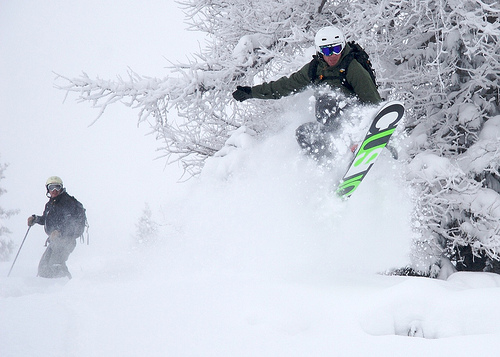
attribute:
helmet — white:
[317, 30, 342, 47]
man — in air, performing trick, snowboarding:
[275, 31, 398, 187]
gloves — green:
[237, 74, 260, 114]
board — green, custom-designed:
[317, 104, 401, 216]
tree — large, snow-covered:
[58, 15, 498, 180]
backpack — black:
[334, 32, 377, 76]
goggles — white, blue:
[295, 44, 356, 57]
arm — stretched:
[224, 57, 318, 111]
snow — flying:
[291, 106, 372, 193]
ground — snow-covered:
[82, 274, 487, 352]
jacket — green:
[254, 58, 373, 128]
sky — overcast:
[9, 12, 174, 66]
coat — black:
[38, 192, 85, 255]